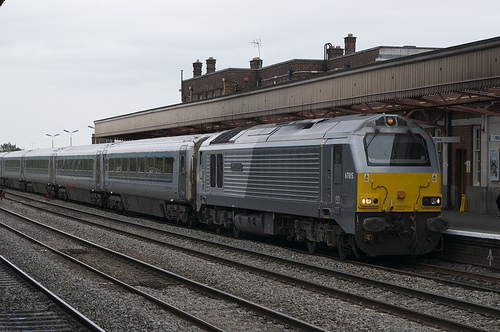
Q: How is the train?
A: Motionless.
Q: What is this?
A: A train.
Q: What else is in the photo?
A: A rail.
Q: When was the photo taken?
A: Daytime.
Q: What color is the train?
A: Grey.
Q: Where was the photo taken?
A: At a train station.